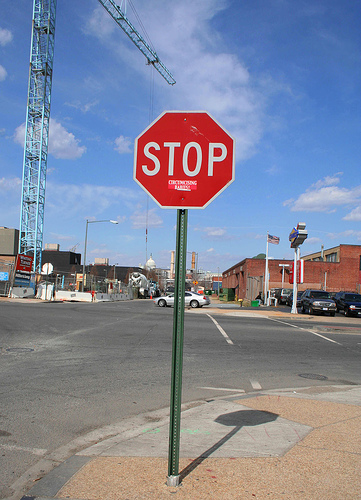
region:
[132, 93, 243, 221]
the stop sign on the pole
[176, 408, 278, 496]
the shadow on the ground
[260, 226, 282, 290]
the flag blowing in the wind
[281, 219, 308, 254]
the logo on the pole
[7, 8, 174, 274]
the metal crane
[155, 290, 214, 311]
the silver car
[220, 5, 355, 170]
the sky is blue and clear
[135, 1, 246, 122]
the clouds in the sky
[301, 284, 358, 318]
the cars are parked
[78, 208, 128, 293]
the street light over the street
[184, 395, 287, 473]
a shadow of a stop sign on the floor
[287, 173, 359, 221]
a cloud in the sky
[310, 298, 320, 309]
the head light of a car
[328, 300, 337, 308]
the head light of a car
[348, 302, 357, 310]
the head light of a car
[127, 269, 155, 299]
a white cement mixer on a street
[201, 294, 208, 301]
the tail light of a car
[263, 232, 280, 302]
a flag pole with the American flag flying at it's top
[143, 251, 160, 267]
a dome of a government building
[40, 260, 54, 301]
the back of a stop sign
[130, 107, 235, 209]
Stop sign is red and white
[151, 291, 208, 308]
Silver car on the street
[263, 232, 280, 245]
American flag is flying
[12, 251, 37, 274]
Red sign is square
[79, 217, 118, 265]
Street lamp in the background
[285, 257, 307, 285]
Red and white banner on building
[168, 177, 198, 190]
Small sticker on stop sign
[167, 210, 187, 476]
Sign post is green and metal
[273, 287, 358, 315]
Vehicles in the parking lot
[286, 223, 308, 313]
Large sign on a white pole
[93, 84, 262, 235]
the sign is red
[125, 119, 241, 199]
the letters are white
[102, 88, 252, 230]
the sign is an octagon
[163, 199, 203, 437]
the sign is on a pole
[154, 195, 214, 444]
the pole is green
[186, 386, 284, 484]
a shadow on the sidewalk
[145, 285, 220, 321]
the car is grey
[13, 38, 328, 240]
the sky is partly cloudy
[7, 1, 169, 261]
a crane to the left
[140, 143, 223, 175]
white letters on the stop sign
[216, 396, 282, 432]
a shadow on the ground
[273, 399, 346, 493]
the sidewalk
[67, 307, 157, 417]
the street is grey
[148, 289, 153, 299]
a cone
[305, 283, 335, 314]
a suv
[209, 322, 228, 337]
white line in the street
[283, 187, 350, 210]
the cloud in the sky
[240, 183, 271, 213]
the sky is clear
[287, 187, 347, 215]
the cloud is white